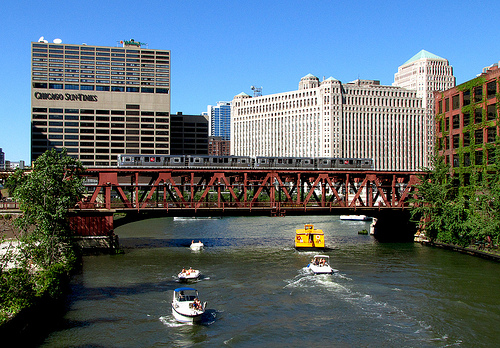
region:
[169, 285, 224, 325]
Thuis is a small boat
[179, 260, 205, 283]
This is a small boat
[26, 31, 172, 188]
This is a building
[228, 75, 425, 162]
This is a buildnig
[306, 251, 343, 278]
This is a small boat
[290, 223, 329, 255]
This is a boat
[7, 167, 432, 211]
this is a bridge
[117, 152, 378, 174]
this is a train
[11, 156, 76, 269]
this is a tree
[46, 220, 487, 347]
this is a water body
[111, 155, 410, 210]
covered bridge with a train on top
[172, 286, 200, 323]
white and blue boat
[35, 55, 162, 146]
Chicago Sun Times building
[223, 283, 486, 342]
river water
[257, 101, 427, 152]
white building with many windows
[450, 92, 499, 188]
ivy climbing a brown building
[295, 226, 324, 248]
yellow boat under the bridge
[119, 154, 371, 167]
silver elevated train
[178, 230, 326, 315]
group of five boats in the water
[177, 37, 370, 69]
clear sunny skies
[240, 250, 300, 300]
part of a water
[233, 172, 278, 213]
part of a bridge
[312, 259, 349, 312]
part of a splash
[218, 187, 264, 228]
edge of a bridge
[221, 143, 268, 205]
part of a bridge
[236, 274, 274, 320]
part of a water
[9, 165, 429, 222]
a red metal bridge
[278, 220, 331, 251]
a yellow boat in water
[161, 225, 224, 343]
three boats in the water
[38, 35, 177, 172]
a tall building with several levels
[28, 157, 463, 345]
a body of water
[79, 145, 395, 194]
a train crossing a bridge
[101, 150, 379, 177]
a silver train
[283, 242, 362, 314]
a wake in the water from a boat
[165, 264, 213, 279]
people on a white boat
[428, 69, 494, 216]
green vines growing up a building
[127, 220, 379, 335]
Boats on a river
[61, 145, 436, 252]
A bridge over a river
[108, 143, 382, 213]
A train on a bridge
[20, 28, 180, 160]
A newspaper's building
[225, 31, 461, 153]
A white office building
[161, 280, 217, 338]
A white boat with a blue roof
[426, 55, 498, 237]
A red building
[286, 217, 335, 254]
A yellow boat on a river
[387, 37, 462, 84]
The top of a building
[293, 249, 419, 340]
A boat leaving a wake in a river